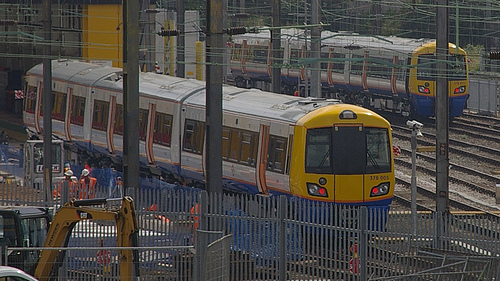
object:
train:
[16, 52, 402, 252]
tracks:
[300, 108, 497, 280]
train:
[225, 22, 477, 123]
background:
[135, 7, 499, 94]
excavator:
[3, 192, 145, 279]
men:
[79, 165, 104, 206]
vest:
[79, 176, 98, 196]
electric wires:
[3, 4, 498, 77]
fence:
[7, 175, 498, 277]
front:
[291, 104, 399, 257]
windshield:
[305, 121, 395, 175]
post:
[430, 1, 459, 254]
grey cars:
[18, 45, 298, 231]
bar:
[203, 2, 229, 278]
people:
[44, 158, 208, 238]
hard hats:
[64, 168, 91, 176]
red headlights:
[317, 183, 381, 198]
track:
[378, 106, 496, 280]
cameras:
[401, 112, 427, 241]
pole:
[409, 129, 423, 248]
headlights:
[307, 182, 394, 201]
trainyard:
[4, 149, 243, 279]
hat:
[79, 166, 90, 177]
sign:
[13, 85, 26, 104]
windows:
[24, 79, 290, 173]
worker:
[145, 201, 171, 223]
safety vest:
[144, 213, 168, 225]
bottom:
[242, 190, 393, 229]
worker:
[58, 167, 80, 200]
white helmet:
[62, 168, 75, 177]